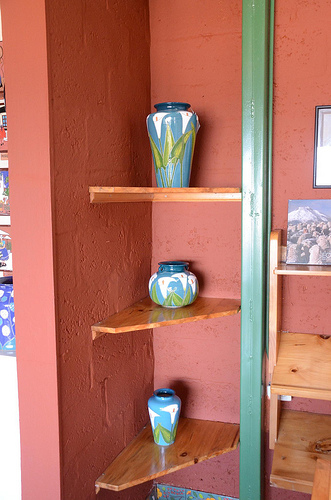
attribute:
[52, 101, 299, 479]
shelves — brown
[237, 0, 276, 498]
pole — green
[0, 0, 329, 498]
wall — pink, concrete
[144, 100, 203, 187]
vase — blue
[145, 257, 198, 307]
vase — blue, small, circular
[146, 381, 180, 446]
vase — blue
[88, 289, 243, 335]
shelf — wooden, in middle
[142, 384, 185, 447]
vase — small, blue, flowered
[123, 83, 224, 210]
vase. — floral, tall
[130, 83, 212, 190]
vase — blue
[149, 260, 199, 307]
vase — white, blue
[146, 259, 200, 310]
pot — blue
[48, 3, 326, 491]
wall — hanging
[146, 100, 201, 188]
vases — blue white & green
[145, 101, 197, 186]
vase — blue, white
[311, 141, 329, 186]
light — shining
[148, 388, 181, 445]
vase — blue, white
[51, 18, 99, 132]
wall — red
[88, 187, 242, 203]
shelf — top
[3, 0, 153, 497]
wall — concrete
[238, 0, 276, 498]
beam — green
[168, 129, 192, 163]
leaf — green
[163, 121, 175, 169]
leaf — green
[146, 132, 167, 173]
leaf — green